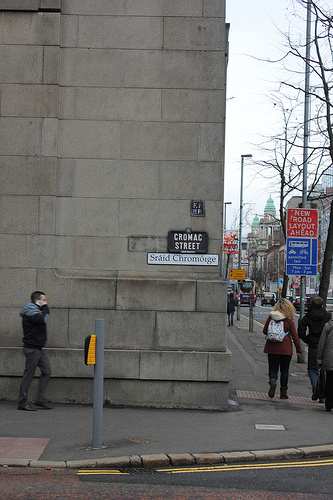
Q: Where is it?
A: This is at the street.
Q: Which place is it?
A: It is a street.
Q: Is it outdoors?
A: Yes, it is outdoors.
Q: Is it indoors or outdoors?
A: It is outdoors.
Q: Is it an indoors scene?
A: No, it is outdoors.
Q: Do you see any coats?
A: Yes, there is a coat.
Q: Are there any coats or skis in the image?
A: Yes, there is a coat.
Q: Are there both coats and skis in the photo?
A: No, there is a coat but no skis.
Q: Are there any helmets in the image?
A: No, there are no helmets.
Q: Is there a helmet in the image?
A: No, there are no helmets.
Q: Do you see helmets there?
A: No, there are no helmets.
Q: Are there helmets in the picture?
A: No, there are no helmets.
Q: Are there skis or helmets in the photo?
A: No, there are no helmets or skis.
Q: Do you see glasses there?
A: No, there are no glasses.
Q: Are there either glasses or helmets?
A: No, there are no glasses or helmets.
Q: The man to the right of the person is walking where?
A: The man is walking on the street.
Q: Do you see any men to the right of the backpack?
A: Yes, there is a man to the right of the backpack.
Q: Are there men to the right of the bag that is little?
A: Yes, there is a man to the right of the backpack.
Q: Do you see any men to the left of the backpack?
A: No, the man is to the right of the backpack.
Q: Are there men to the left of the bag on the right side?
A: No, the man is to the right of the backpack.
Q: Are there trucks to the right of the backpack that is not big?
A: No, there is a man to the right of the backpack.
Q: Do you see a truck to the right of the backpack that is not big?
A: No, there is a man to the right of the backpack.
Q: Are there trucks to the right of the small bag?
A: No, there is a man to the right of the backpack.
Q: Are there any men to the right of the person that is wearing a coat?
A: Yes, there is a man to the right of the person.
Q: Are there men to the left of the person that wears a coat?
A: No, the man is to the right of the person.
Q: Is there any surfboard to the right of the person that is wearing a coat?
A: No, there is a man to the right of the person.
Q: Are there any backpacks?
A: Yes, there is a backpack.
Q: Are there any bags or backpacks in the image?
A: Yes, there is a backpack.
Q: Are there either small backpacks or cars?
A: Yes, there is a small backpack.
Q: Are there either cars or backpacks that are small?
A: Yes, the backpack is small.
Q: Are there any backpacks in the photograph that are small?
A: Yes, there is a small backpack.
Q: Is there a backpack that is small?
A: Yes, there is a backpack that is small.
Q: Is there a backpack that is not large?
A: Yes, there is a small backpack.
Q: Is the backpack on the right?
A: Yes, the backpack is on the right of the image.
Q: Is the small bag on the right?
A: Yes, the backpack is on the right of the image.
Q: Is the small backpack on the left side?
A: No, the backpack is on the right of the image.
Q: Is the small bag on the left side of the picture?
A: No, the backpack is on the right of the image.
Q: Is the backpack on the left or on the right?
A: The backpack is on the right of the image.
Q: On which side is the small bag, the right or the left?
A: The backpack is on the right of the image.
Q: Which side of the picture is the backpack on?
A: The backpack is on the right of the image.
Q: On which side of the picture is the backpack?
A: The backpack is on the right of the image.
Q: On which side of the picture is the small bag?
A: The backpack is on the right of the image.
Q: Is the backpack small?
A: Yes, the backpack is small.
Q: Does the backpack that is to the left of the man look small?
A: Yes, the backpack is small.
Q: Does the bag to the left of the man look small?
A: Yes, the backpack is small.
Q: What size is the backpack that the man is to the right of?
A: The backpack is small.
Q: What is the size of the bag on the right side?
A: The backpack is small.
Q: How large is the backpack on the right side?
A: The backpack is small.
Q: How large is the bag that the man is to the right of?
A: The backpack is small.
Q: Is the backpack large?
A: No, the backpack is small.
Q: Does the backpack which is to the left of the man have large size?
A: No, the backpack is small.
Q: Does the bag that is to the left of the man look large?
A: No, the backpack is small.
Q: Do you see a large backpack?
A: No, there is a backpack but it is small.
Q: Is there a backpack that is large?
A: No, there is a backpack but it is small.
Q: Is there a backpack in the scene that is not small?
A: No, there is a backpack but it is small.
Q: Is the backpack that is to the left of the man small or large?
A: The backpack is small.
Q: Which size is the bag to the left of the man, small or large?
A: The backpack is small.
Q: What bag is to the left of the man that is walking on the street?
A: The bag is a backpack.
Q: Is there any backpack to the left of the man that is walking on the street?
A: Yes, there is a backpack to the left of the man.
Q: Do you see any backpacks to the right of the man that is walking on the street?
A: No, the backpack is to the left of the man.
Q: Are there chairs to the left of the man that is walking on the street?
A: No, there is a backpack to the left of the man.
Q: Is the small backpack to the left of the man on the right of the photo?
A: Yes, the backpack is to the left of the man.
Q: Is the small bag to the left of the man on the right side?
A: Yes, the backpack is to the left of the man.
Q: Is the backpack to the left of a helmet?
A: No, the backpack is to the left of the man.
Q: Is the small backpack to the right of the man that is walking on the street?
A: No, the backpack is to the left of the man.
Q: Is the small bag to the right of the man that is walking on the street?
A: No, the backpack is to the left of the man.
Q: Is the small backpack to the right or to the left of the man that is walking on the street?
A: The backpack is to the left of the man.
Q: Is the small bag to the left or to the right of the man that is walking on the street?
A: The backpack is to the left of the man.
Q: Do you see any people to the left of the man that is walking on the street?
A: Yes, there is a person to the left of the man.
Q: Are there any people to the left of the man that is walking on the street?
A: Yes, there is a person to the left of the man.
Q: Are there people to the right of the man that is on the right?
A: No, the person is to the left of the man.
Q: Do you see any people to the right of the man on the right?
A: No, the person is to the left of the man.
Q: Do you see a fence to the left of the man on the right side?
A: No, there is a person to the left of the man.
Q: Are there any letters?
A: Yes, there are letters.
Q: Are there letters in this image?
A: Yes, there are letters.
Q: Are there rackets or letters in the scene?
A: Yes, there are letters.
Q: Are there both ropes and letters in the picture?
A: No, there are letters but no ropes.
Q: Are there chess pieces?
A: No, there are no chess pieces.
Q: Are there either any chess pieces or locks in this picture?
A: No, there are no chess pieces or locks.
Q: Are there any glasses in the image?
A: No, there are no glasses.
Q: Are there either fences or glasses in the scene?
A: No, there are no glasses or fences.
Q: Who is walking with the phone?
A: The man is walking with the phone.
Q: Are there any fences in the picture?
A: No, there are no fences.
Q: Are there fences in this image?
A: No, there are no fences.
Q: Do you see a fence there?
A: No, there are no fences.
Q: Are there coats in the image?
A: Yes, there is a coat.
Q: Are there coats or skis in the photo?
A: Yes, there is a coat.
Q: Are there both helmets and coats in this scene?
A: No, there is a coat but no helmets.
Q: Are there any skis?
A: No, there are no skis.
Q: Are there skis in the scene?
A: No, there are no skis.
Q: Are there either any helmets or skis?
A: No, there are no skis or helmets.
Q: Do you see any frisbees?
A: No, there are no frisbees.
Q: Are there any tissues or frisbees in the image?
A: No, there are no frisbees or tissues.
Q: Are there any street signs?
A: Yes, there is a street sign.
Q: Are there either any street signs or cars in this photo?
A: Yes, there is a street sign.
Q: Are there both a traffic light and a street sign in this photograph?
A: No, there is a street sign but no traffic lights.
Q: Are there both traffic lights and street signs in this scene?
A: No, there is a street sign but no traffic lights.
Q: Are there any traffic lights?
A: No, there are no traffic lights.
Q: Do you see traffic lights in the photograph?
A: No, there are no traffic lights.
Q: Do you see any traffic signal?
A: No, there are no traffic lights.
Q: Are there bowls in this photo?
A: No, there are no bowls.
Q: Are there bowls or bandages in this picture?
A: No, there are no bowls or bandages.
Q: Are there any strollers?
A: No, there are no strollers.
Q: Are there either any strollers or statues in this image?
A: No, there are no strollers or statues.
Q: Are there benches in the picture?
A: No, there are no benches.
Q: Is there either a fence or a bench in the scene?
A: No, there are no benches or fences.